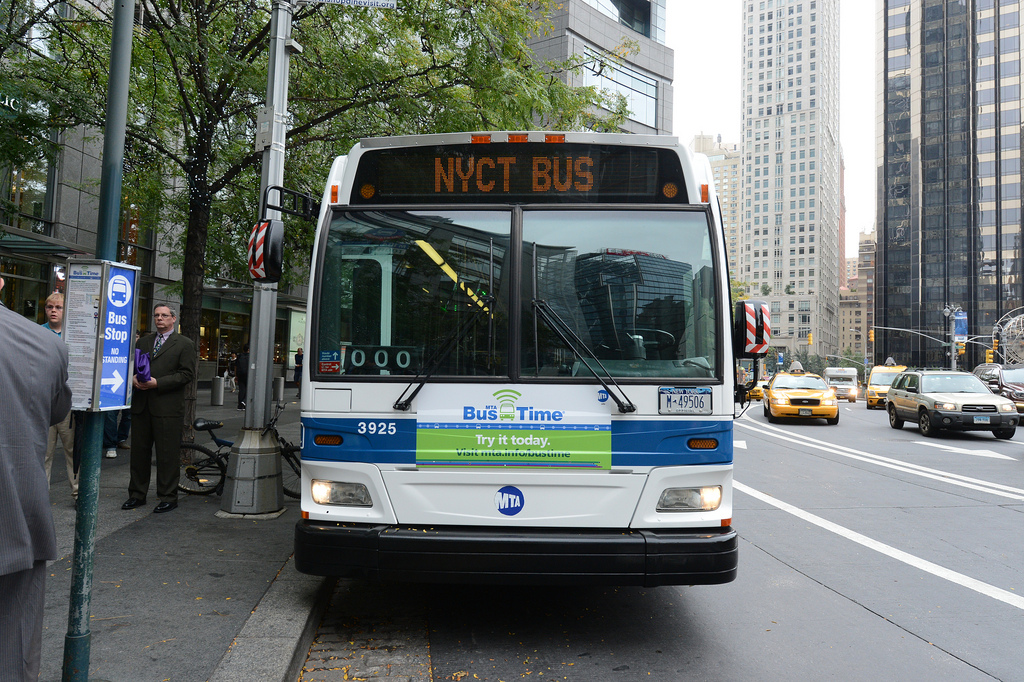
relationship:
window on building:
[756, 221, 769, 237] [733, 0, 854, 385]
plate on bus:
[653, 387, 718, 414] [303, 122, 747, 607]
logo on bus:
[495, 482, 524, 514] [303, 122, 747, 607]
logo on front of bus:
[462, 384, 562, 422] [303, 122, 747, 607]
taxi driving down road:
[760, 369, 841, 424] [429, 371, 1021, 678]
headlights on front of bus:
[776, 396, 834, 412] [303, 122, 747, 607]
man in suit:
[124, 298, 203, 517] [119, 334, 204, 518]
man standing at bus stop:
[124, 298, 203, 517] [46, 155, 187, 674]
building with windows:
[734, 5, 848, 341] [748, 12, 788, 39]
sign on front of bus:
[355, 133, 682, 209] [303, 122, 747, 607]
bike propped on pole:
[179, 407, 306, 516] [210, 259, 293, 528]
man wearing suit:
[124, 298, 202, 517] [127, 325, 199, 509]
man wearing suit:
[0, 267, 73, 675] [0, 303, 72, 679]